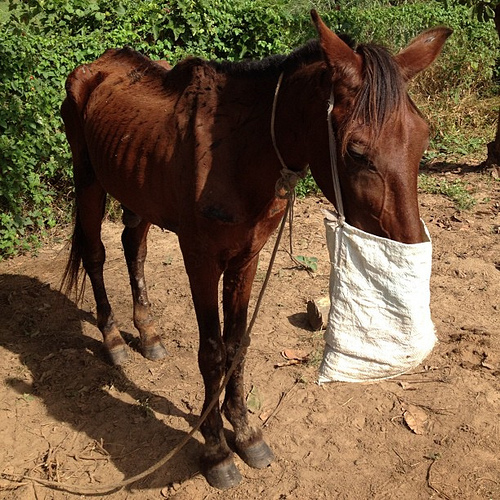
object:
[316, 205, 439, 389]
feedbag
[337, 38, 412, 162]
hair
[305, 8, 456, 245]
head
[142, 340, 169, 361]
hoof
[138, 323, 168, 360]
foot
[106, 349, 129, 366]
hoof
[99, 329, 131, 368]
foot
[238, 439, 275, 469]
hoof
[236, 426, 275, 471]
foot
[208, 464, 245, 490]
hoof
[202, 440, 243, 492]
foot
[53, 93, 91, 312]
tail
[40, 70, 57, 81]
leaf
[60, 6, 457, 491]
horse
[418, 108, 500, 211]
grass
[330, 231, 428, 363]
feed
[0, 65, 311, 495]
rope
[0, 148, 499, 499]
soil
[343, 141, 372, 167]
eyes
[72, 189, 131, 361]
leg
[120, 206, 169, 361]
leg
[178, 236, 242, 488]
leg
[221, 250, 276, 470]
leg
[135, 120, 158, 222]
ribs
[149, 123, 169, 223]
ribs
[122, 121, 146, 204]
ribs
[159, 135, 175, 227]
ribs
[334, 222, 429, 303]
muzzle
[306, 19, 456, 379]
front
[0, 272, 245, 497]
shadow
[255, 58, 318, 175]
neck